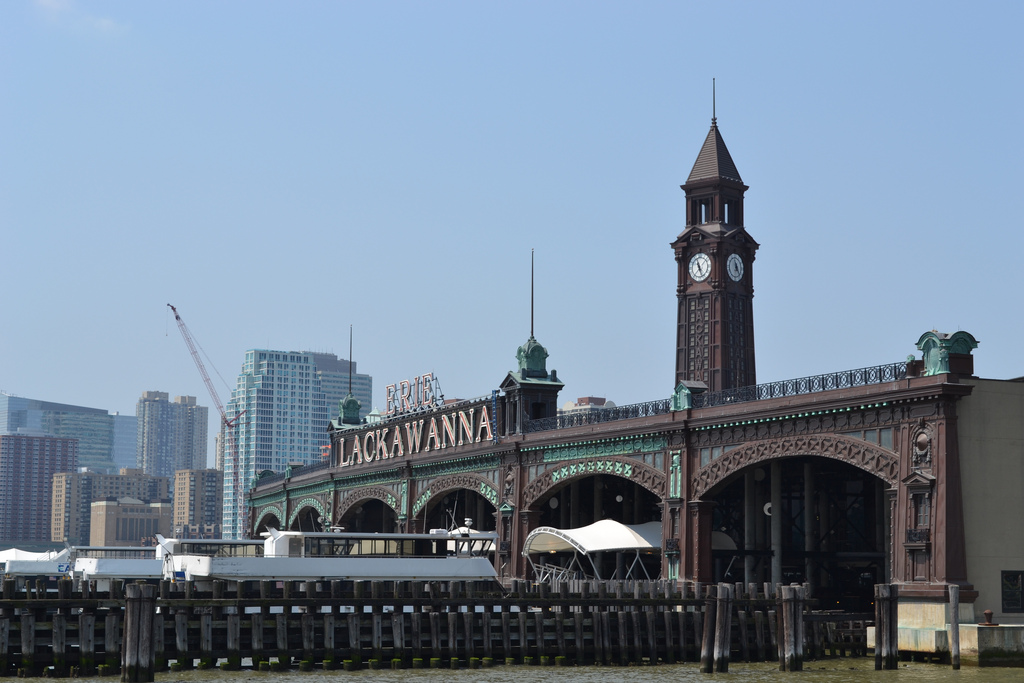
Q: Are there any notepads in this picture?
A: No, there are no notepads.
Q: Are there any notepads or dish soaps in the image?
A: No, there are no notepads or dish soaps.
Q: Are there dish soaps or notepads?
A: No, there are no notepads or dish soaps.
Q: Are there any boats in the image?
A: Yes, there is a boat.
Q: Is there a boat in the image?
A: Yes, there is a boat.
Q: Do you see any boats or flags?
A: Yes, there is a boat.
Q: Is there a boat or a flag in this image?
A: Yes, there is a boat.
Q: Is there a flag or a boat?
A: Yes, there is a boat.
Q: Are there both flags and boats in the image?
A: No, there is a boat but no flags.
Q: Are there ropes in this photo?
A: No, there are no ropes.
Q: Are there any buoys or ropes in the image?
A: No, there are no ropes or buoys.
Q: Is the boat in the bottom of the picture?
A: Yes, the boat is in the bottom of the image.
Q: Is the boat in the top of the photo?
A: No, the boat is in the bottom of the image.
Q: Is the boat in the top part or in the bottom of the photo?
A: The boat is in the bottom of the image.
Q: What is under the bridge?
A: The boat is under the bridge.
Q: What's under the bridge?
A: The boat is under the bridge.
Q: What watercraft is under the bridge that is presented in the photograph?
A: The watercraft is a boat.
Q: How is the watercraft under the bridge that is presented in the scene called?
A: The watercraft is a boat.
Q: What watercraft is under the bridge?
A: The watercraft is a boat.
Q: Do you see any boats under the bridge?
A: Yes, there is a boat under the bridge.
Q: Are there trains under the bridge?
A: No, there is a boat under the bridge.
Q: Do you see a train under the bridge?
A: No, there is a boat under the bridge.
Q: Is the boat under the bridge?
A: Yes, the boat is under the bridge.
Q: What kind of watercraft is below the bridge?
A: The watercraft is a boat.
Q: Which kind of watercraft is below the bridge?
A: The watercraft is a boat.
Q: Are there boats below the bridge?
A: Yes, there is a boat below the bridge.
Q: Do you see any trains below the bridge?
A: No, there is a boat below the bridge.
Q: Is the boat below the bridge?
A: Yes, the boat is below the bridge.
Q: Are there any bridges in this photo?
A: Yes, there is a bridge.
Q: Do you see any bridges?
A: Yes, there is a bridge.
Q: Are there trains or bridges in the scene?
A: Yes, there is a bridge.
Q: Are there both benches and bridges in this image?
A: No, there is a bridge but no benches.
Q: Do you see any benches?
A: No, there are no benches.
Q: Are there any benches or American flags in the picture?
A: No, there are no benches or American flags.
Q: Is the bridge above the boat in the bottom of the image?
A: Yes, the bridge is above the boat.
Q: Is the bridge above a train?
A: No, the bridge is above the boat.